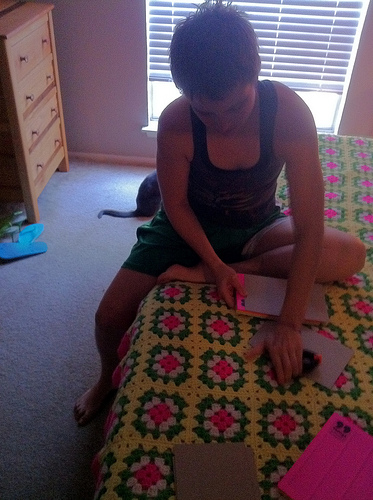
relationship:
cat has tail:
[93, 164, 163, 222] [96, 203, 144, 220]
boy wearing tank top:
[71, 1, 366, 429] [176, 77, 280, 222]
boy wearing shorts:
[71, 1, 366, 429] [121, 206, 288, 277]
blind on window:
[147, 3, 363, 95] [140, 1, 372, 137]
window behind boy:
[140, 1, 372, 137] [71, 1, 366, 429]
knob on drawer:
[40, 35, 50, 46] [8, 22, 51, 85]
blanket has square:
[89, 125, 370, 499] [143, 343, 196, 388]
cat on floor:
[93, 164, 163, 222] [2, 159, 164, 498]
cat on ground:
[93, 164, 163, 222] [2, 159, 164, 498]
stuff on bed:
[169, 269, 372, 500] [91, 126, 371, 499]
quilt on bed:
[89, 125, 370, 499] [91, 126, 371, 499]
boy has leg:
[71, 1, 366, 429] [71, 206, 179, 428]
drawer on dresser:
[8, 22, 51, 85] [1, 3, 73, 226]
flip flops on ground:
[1, 219, 49, 263] [2, 159, 164, 498]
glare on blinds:
[149, 3, 365, 130] [147, 3, 363, 95]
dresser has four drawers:
[1, 3, 73, 226] [7, 21, 62, 187]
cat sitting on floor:
[93, 164, 163, 222] [2, 159, 164, 498]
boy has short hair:
[71, 1, 366, 429] [169, 3, 261, 100]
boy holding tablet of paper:
[71, 1, 366, 429] [232, 271, 332, 326]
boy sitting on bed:
[71, 1, 366, 429] [91, 126, 371, 499]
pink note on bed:
[274, 408, 371, 499] [91, 126, 371, 499]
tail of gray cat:
[96, 203, 144, 220] [93, 164, 163, 222]